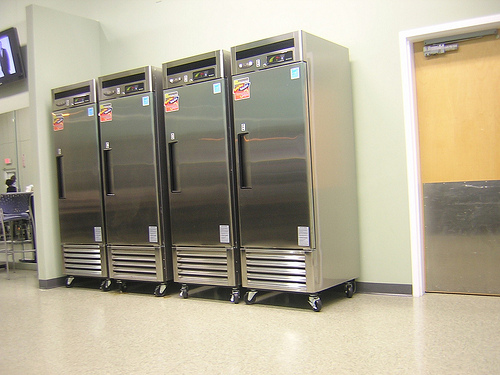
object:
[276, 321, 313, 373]
reflections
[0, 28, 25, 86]
television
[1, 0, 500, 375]
room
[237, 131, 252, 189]
handle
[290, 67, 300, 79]
logo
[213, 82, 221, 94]
logo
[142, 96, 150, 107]
logo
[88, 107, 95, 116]
logo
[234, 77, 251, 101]
logo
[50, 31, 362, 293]
fridge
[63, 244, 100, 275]
vent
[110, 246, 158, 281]
vent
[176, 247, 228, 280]
vent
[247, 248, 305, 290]
vent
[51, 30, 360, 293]
machine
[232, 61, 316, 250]
door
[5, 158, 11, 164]
exit sign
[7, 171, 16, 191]
door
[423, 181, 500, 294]
metal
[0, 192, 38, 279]
chair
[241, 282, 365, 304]
tree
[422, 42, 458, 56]
hinge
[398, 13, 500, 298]
door frame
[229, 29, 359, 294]
container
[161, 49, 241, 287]
container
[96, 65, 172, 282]
container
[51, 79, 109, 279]
container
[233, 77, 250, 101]
picture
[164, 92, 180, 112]
picture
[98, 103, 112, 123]
picture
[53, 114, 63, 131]
picture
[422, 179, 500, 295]
bottom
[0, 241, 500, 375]
floor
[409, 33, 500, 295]
door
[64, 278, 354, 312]
wheels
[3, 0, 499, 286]
wall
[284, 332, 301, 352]
light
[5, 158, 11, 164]
sign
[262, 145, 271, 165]
part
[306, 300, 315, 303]
part